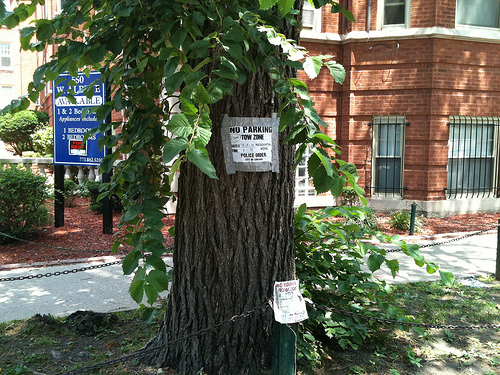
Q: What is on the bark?
A: Paper signs.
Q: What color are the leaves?
A: Green.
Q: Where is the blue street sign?
A: Left of tree.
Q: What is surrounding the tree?
A: Fence with chain.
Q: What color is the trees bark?
A: Brown.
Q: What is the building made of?
A: Brick.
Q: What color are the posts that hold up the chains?
A: Green.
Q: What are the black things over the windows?
A: Bars.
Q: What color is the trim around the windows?
A: White.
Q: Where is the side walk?
A: Behind tree.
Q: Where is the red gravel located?
A: In front of building.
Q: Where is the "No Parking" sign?
A: Taped to tree.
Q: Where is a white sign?
A: Taped to the tree.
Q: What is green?
A: Leaves.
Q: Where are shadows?
A: On building.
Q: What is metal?
A: Chain fence.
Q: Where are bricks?
A: On the building.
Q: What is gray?
A: Tape on white sign.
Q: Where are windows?
A: On building.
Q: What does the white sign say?
A: "NO PARKING".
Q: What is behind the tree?
A: Sidewalk.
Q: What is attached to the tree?
A: Signs.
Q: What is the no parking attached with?
A: Duct tape.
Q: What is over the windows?
A: Black bars.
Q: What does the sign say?
A: No parking.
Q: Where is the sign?
A: On the tree.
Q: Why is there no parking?
A: Tow zone.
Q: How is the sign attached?
A: Duct tape.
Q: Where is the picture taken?
A: In a city.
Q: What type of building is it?
A: Apartment.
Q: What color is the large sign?
A: Blue.